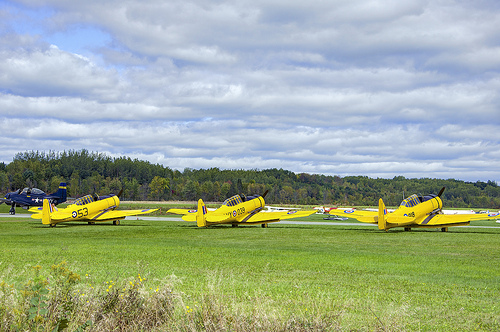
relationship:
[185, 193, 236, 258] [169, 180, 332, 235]
tail on plane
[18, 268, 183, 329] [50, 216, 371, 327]
plants in field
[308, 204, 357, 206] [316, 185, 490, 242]
sticker on plane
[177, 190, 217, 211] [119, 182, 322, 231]
symbol on plane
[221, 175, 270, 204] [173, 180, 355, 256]
cockpit with airplanes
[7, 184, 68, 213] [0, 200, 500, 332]
airplane on field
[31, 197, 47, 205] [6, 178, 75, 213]
star on plane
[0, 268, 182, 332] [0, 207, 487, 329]
plants are on field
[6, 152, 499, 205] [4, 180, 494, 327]
trees beyond field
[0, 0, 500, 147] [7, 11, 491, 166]
clouds are in sky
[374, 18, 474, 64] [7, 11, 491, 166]
clouds are in sky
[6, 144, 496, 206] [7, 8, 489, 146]
trees under sky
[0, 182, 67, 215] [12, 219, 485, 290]
airplane parked on lawn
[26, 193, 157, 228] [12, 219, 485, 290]
airplane parked on lawn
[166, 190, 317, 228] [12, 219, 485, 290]
airplane parked on lawn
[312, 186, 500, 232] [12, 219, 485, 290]
airplane parked on lawn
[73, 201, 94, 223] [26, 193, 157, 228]
number 53 on airplane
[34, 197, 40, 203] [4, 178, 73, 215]
star on airplane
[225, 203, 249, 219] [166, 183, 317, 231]
number on airplane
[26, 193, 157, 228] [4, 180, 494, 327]
airplane sitting on field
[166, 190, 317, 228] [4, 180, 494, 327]
airplane sitting on field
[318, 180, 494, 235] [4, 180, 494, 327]
plane sitting on field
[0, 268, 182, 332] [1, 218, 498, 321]
plants next to field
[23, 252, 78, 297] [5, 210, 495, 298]
flowers next to field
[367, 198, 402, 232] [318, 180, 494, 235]
tail on plane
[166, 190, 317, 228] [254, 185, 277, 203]
airplane has propeller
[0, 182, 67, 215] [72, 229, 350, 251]
airplane are on grass